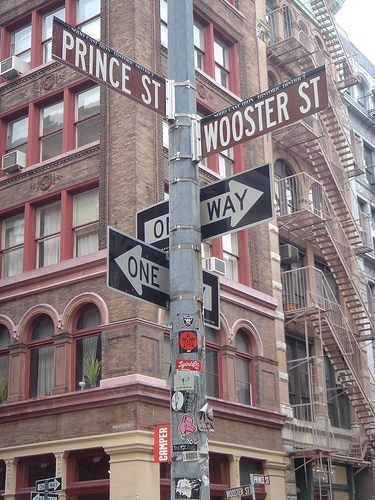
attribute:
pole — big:
[164, 0, 209, 499]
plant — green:
[69, 354, 115, 406]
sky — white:
[328, 0, 374, 61]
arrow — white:
[144, 176, 263, 227]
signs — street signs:
[44, 15, 349, 158]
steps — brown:
[265, 84, 374, 445]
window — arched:
[43, 294, 121, 389]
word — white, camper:
[157, 426, 168, 464]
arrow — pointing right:
[36, 471, 68, 492]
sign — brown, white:
[41, 11, 177, 124]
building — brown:
[3, 0, 281, 500]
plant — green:
[81, 338, 114, 397]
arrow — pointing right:
[135, 173, 275, 234]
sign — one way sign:
[132, 160, 275, 250]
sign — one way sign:
[103, 223, 222, 330]